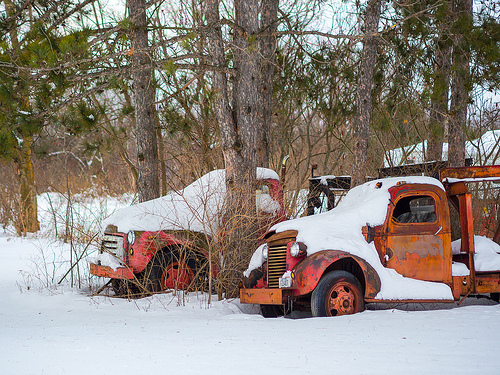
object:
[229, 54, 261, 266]
tree bark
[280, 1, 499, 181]
trees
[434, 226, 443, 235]
handle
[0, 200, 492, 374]
ground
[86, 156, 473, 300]
truck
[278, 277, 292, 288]
plate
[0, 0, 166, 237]
tree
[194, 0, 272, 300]
tree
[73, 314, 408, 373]
sun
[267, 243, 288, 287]
rusty grill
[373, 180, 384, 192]
lights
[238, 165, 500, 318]
old truck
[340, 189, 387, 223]
windshield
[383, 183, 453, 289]
door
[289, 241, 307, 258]
light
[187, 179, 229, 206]
windshield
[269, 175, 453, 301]
hood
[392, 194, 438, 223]
window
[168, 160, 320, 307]
branches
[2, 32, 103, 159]
tree needles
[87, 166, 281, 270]
hood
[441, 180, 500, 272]
rack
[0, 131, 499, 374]
snow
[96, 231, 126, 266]
grill